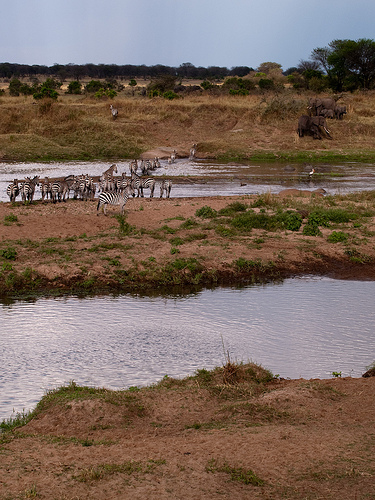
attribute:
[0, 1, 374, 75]
sky — blue, hazy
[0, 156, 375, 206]
river — water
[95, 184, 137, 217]
zebra — black, white, standing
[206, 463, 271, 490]
grass — green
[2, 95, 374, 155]
grass — brown, dead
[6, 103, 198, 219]
zebras — herd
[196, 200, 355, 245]
shrubs — green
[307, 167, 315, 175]
bird — white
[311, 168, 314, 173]
beak — yellow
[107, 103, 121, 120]
zebra — coming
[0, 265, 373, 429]
water — river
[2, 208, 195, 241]
dirt — tan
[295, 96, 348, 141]
elephants — together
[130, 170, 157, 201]
zebra — black, standing, white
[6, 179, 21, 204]
zebra — standing, black, white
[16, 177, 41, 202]
zebra — black, standing, white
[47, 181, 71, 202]
zebra — black, standing, white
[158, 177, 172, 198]
zebra — black, standing, white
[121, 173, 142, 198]
zebra — black, standing, white